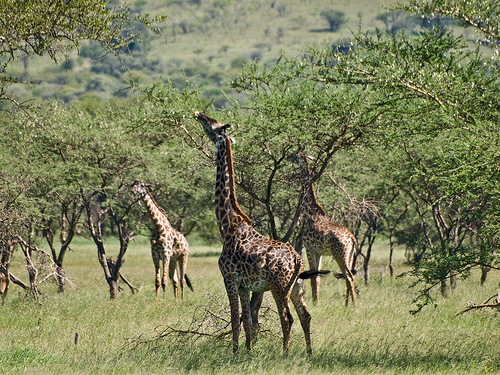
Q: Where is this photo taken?
A: The wild.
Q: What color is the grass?
A: Green.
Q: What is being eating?
A: The tree.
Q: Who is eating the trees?
A: The giraffes.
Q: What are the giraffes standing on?
A: Their legs.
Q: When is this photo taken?
A: Daytime.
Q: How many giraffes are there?
A: Three.